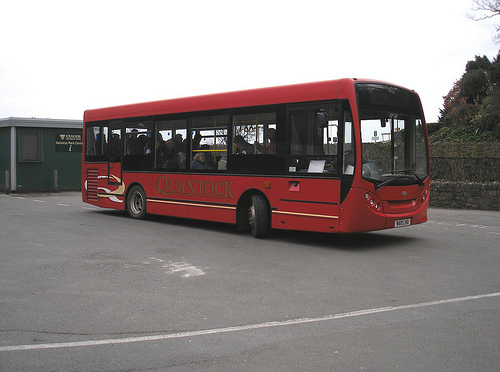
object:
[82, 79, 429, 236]
bus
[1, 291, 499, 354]
line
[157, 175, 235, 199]
letters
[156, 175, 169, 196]
q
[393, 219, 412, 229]
tag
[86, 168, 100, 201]
vent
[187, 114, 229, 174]
window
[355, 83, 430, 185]
windshield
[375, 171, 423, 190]
wipers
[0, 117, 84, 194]
building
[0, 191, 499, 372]
pavement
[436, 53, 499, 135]
tree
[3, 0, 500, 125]
sky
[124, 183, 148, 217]
wheel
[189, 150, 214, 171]
passenger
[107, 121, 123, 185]
door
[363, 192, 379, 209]
headlights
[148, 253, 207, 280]
spill